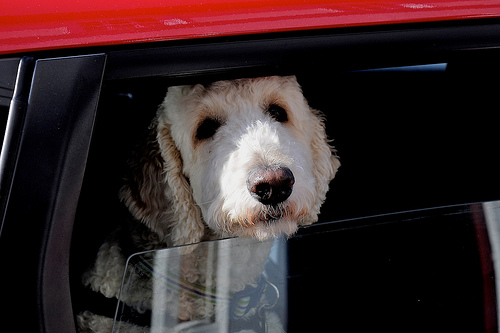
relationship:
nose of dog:
[247, 167, 293, 204] [76, 74, 339, 333]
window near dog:
[107, 197, 500, 331] [76, 74, 339, 333]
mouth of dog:
[247, 208, 296, 232] [76, 74, 339, 333]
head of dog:
[119, 74, 345, 253] [76, 74, 339, 333]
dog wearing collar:
[76, 74, 339, 333] [124, 234, 282, 323]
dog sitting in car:
[76, 74, 339, 333] [2, 1, 499, 327]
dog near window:
[76, 74, 339, 333] [107, 197, 500, 331]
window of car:
[107, 197, 500, 331] [2, 1, 499, 327]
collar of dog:
[124, 234, 282, 323] [76, 74, 339, 333]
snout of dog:
[181, 142, 376, 258] [130, 65, 373, 246]